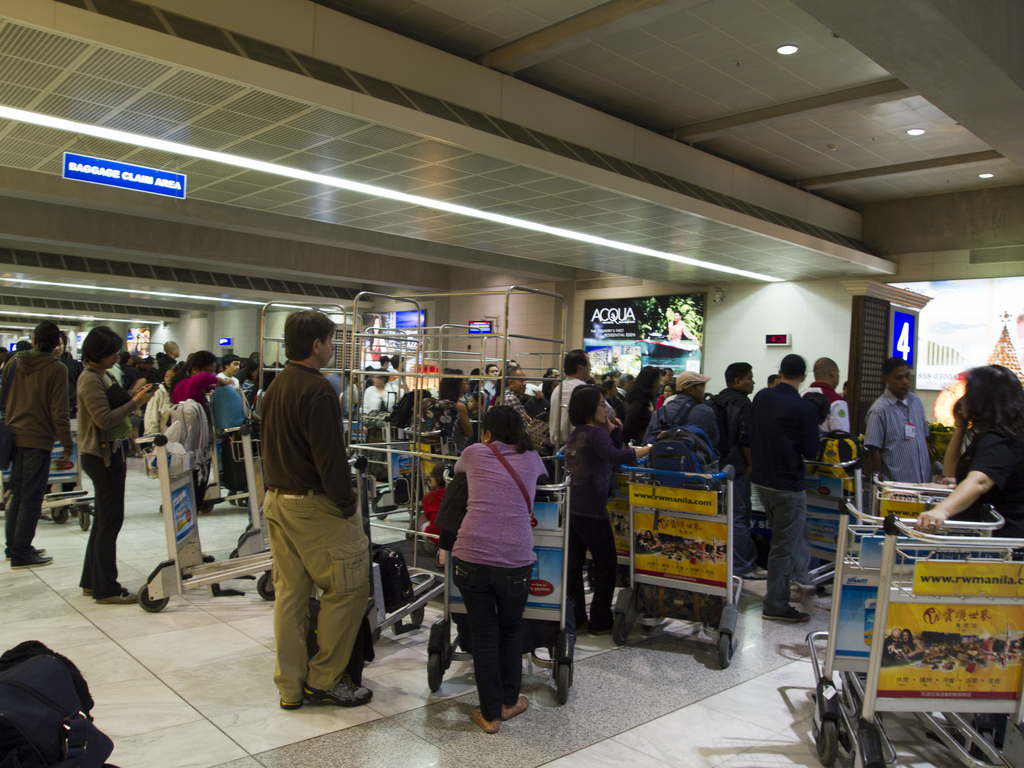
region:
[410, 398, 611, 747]
a woman wears a pink top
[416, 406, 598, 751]
a woman on front a cart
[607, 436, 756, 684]
the cart is yellow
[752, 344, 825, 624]
man wears a black sweater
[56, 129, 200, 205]
a blue sign on the ceiling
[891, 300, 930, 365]
the number 4 is white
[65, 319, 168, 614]
woman is looking a cell phone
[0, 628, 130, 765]
a blue bag on the ground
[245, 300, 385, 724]
man has hands on the pocket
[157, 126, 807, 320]
white light in ceiling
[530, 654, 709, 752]
grey tile on floor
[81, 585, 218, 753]
white tile on floor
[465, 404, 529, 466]
woman has black hair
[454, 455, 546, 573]
woman has pink shirt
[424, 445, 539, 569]
woman has red bag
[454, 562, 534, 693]
woman has black pants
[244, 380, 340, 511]
man has brown shirt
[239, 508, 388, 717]
man has brown pants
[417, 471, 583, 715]
woman leaning on cart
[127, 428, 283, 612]
luggage cart on sitting waiting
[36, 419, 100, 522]
luggage cart on sitting waiting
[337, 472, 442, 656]
luggage cart on sitting waiting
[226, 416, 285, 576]
luggage cart on sitting waiting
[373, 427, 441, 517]
luggage cart on sitting waiting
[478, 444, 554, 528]
strap is running across the back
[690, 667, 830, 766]
shadow from the cart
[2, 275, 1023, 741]
a crowd of people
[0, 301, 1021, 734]
people standing at the airport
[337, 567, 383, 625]
knee is slightly bent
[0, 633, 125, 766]
bag laying on the ground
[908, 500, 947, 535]
hand is on the cart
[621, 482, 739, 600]
advertisement on the cart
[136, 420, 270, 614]
The luggage cart in front of the lady.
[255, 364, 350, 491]
Th shirt is brown.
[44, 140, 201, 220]
A blue sign hanging from the ceiling.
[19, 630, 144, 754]
A black bag on the floor.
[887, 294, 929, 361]
The sign has a number 4 on it.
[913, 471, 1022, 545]
A person hand on the luggage cart.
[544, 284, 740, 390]
A sign against the wall.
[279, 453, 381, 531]
man has his hand in his pocket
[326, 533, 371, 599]
man's pants have pockets on the sides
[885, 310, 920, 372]
4 written in white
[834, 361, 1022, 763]
woman standing next to luggage carts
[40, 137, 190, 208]
BAGGAGE CLAIM AREA written on the overhead sign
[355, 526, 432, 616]
luggage on the cart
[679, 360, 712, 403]
man is wearing a hat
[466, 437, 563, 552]
woman has a red strap across her back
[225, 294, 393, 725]
man holding luggage cart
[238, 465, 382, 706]
khaki cargo pants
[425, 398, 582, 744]
woman leaning on luggage cart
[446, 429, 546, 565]
short sleeved pink shirt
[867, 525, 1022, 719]
yellow back of luggage cart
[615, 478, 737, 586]
yellow back of luggage cart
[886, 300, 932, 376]
blue 4 sign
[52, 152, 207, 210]
blue sign hanging from ceiling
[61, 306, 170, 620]
woman looking at cell phone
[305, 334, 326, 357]
Ear of a man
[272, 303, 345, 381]
Head of a man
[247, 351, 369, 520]
Shirt on a man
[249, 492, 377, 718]
Pants on a man